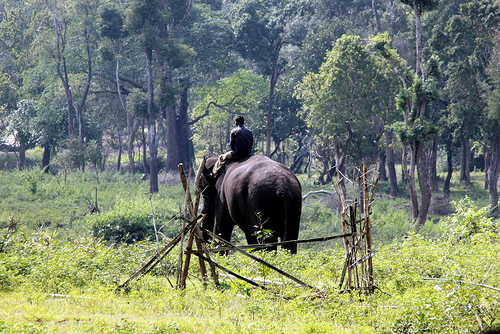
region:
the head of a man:
[224, 102, 258, 132]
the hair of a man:
[219, 96, 266, 131]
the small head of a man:
[226, 100, 260, 139]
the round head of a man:
[231, 100, 262, 136]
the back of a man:
[226, 96, 260, 159]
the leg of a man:
[200, 142, 247, 184]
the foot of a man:
[199, 159, 224, 189]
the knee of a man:
[214, 140, 226, 171]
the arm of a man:
[214, 118, 245, 150]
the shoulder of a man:
[228, 105, 255, 147]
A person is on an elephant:
[41, 62, 437, 325]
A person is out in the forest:
[18, 65, 465, 311]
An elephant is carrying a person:
[23, 65, 469, 313]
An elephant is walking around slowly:
[43, 63, 425, 290]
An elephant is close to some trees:
[45, 90, 440, 285]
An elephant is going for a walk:
[45, 65, 445, 310]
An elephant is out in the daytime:
[46, 65, 381, 303]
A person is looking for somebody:
[28, 75, 455, 286]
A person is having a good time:
[28, 61, 436, 298]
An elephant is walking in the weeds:
[73, 75, 399, 270]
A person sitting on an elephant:
[224, 111, 257, 156]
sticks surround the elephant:
[160, 162, 446, 307]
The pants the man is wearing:
[216, 153, 236, 168]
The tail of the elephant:
[282, 183, 289, 246]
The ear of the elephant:
[198, 151, 208, 194]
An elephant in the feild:
[184, 140, 311, 266]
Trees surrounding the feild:
[10, 10, 497, 170]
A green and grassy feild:
[14, 171, 495, 316]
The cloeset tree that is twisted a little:
[389, 0, 440, 240]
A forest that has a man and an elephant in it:
[9, 10, 496, 330]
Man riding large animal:
[182, 110, 311, 258]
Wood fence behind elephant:
[126, 155, 382, 300]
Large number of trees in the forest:
[0, 0, 495, 230]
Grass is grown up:
[7, 145, 492, 320]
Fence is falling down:
[101, 147, 388, 307]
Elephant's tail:
[273, 177, 296, 253]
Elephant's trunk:
[182, 155, 218, 252]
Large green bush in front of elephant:
[83, 197, 193, 251]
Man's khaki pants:
[205, 144, 232, 169]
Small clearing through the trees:
[4, 124, 19, 162]